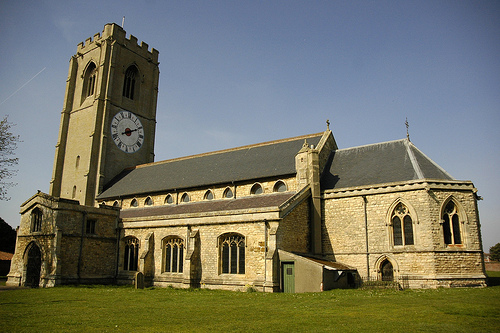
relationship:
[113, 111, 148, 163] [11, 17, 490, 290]
clock on building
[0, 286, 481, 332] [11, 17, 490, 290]
grass outside building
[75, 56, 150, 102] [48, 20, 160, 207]
windows of chapel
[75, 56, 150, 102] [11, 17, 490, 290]
windows of chapel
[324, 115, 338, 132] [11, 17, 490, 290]
crucifix on chapel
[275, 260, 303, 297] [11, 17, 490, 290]
door to chapel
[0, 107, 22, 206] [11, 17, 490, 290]
tree side chapel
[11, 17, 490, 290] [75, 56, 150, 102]
building has windows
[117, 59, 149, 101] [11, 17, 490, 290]
windows on building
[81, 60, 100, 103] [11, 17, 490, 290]
window on building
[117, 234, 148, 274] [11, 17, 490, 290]
window on building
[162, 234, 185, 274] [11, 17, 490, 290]
window on building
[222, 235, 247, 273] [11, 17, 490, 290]
window on building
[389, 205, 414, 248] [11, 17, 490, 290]
window on building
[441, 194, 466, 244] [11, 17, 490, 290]
window on building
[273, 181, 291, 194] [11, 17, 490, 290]
window on building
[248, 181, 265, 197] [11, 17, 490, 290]
window on building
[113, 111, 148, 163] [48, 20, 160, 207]
clock on tower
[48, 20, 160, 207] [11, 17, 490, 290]
tower on building